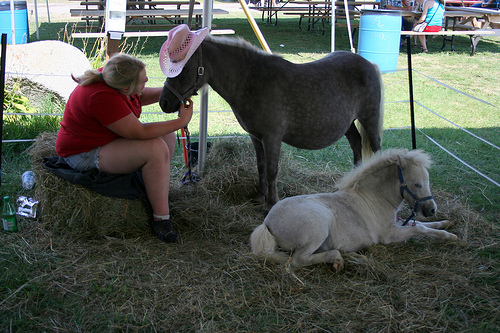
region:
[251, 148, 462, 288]
A white horse lying down in the grass.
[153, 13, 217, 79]
A pink hat is being put on a horse.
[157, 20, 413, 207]
A brown horse standing up.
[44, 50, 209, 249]
A woman is wearing a red shirt.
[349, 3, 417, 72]
The blue trash can is in the sun.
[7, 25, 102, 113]
The huge rock behind the lady.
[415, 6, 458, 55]
A woman wearing a blue shirt.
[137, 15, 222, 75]
hat on the animal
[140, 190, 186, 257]
foot of the lady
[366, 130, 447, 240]
head of the animal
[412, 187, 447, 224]
nose of the animal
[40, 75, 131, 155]
red shirt on the lady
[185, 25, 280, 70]
hair on back of animal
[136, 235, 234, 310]
hay on the ground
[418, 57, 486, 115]
light on the grass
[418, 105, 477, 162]
light and shadow on ground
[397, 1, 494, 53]
woman sitting on a bench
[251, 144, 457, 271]
small white pony laying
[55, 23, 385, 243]
woman sitting next to pony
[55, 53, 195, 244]
woman wearing a red shirt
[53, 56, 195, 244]
woman wearing blue jean shorts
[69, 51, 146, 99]
blonde hair in a ponytail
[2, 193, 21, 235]
green plastic beverage bottle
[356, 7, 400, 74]
green metal trashcan with black bag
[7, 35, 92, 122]
large white boulder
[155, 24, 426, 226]
Brown horse wearing pink hat.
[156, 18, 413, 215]
Brown horse with long tail.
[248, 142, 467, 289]
White horse with mane.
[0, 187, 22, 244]
Bottle with screw off top.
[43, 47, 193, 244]
Lady wearing red t shirt.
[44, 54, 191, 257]
Lady wearing blue jean shorts.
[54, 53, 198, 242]
Lady wearing black tennis shoes.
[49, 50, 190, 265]
Lady wearing white socks inside of tennis.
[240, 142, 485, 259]
This is a horse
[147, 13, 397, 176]
This is a horse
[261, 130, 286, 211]
Leg of a horse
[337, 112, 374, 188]
Leg of a horse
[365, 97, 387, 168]
Leg of a horse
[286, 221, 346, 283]
Leg of a horse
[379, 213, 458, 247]
Leg of a horse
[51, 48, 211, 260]
This is a person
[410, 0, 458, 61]
This is a person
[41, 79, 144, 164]
the shirt is red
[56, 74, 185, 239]
woman sitting on hay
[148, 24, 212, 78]
the hat is pink